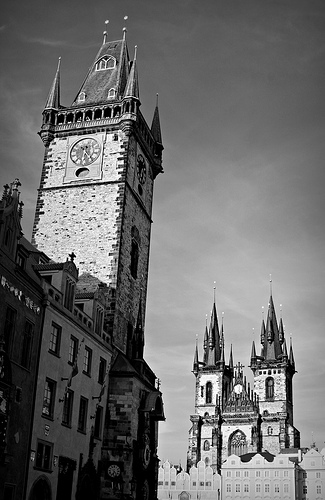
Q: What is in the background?
A: A second cathedral.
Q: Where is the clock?
A: On the cathedral tower.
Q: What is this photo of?
A: Tall cathedral buildings.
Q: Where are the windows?
A: On the buildings.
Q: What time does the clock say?
A: 6:25.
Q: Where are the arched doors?
A: On the cathedral.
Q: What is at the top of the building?
A: Towers with long bars.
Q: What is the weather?
A: Slightly cloudy.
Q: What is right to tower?
A: Church.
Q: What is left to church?
A: Tower.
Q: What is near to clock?
A: Tower.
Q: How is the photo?
A: Clear.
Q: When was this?
A: Daytime.